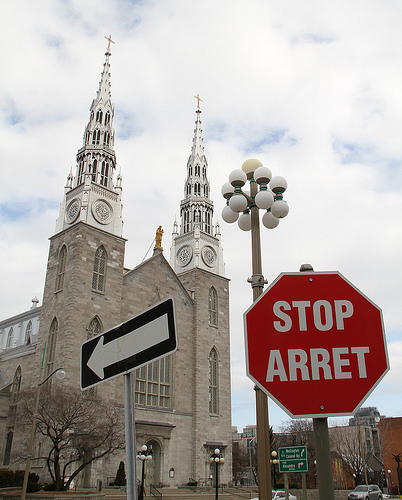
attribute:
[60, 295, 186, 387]
arrow — white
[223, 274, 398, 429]
sign — stop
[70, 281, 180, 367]
sign — road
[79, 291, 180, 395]
sign — black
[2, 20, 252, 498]
church — tall, light colored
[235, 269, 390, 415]
stop sin — red, white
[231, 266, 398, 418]
sign — gren and white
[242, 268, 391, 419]
red sign — board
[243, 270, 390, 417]
board — red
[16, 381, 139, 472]
tree — leaves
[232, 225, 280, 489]
stand — iron, small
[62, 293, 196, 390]
traffic sign — one way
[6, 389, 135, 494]
tree — bare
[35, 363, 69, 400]
lamp — white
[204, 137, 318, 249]
lights — grouped